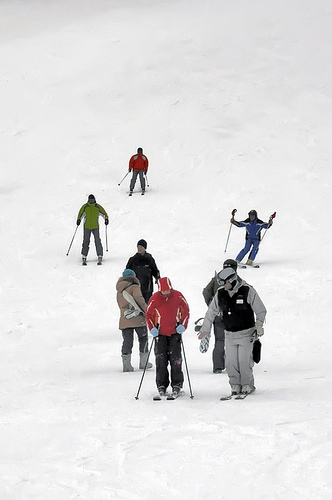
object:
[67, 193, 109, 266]
person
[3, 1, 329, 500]
snow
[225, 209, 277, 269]
person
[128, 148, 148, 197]
person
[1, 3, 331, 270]
hill side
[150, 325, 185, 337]
gloves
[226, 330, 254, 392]
pants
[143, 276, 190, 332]
sweater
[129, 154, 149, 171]
sweater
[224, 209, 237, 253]
ski pole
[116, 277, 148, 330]
coat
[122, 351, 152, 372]
boots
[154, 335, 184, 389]
pants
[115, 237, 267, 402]
people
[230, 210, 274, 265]
poles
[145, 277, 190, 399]
skier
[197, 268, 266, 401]
skier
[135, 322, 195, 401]
ski poles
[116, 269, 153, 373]
woman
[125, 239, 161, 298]
man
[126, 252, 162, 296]
outfit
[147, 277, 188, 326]
stripes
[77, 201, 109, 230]
jacket